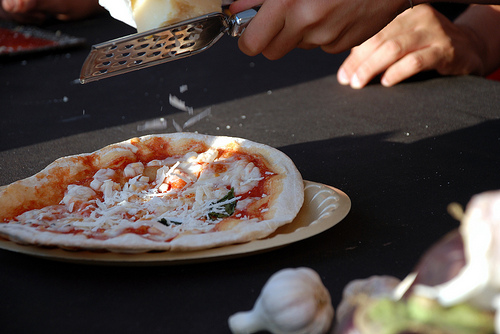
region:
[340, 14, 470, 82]
a hand on the table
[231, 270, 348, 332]
a bulb of white garlic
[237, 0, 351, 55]
a hand holding a spatula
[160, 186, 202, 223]
white cheese sprinkled on a pizza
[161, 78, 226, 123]
crumbs falling on the table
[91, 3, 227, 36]
a hunk of white cheese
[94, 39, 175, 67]
perforated holes in a grater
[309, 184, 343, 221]
a white styrofoam plate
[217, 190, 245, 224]
a leaf to green herb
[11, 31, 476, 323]
a black tablecloth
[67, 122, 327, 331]
a pizza is on the plate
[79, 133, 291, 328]
grated cheese is on the pizza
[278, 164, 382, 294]
the plate is beige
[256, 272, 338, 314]
garlic is on the paper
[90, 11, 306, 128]
cheese is being grated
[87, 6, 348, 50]
the man is holding a grater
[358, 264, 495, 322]
veggies are on the table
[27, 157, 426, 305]
sauce is on the pizza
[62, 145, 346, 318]
crumbled cheese is on the pizza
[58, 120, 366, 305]
the crust is unbaked on the pizza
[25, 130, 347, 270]
pizza on the plate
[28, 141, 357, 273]
the plate on the table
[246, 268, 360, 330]
garlic on the table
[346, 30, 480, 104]
the hand on the table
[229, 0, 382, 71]
the hand holding the grater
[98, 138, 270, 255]
cheese on the pizza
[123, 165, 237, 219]
the cheese is grated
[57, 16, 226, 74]
the cheese on the grater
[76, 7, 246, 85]
the grater is metal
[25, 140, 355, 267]
the plate is styrofoam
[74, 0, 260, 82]
parmesan cheese being grated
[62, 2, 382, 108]
hand grating parmesan cheese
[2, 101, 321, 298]
uncooked personal marghrita pizza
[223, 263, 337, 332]
blurry clove of garlic on a table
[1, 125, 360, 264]
raw pizza on a plate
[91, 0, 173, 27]
hunk of parmesan cheese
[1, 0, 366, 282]
cheese grated onto a pizza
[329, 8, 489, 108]
hand in the distance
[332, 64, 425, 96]
fingers on a resting hand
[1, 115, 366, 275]
pizza ready to go in the oven